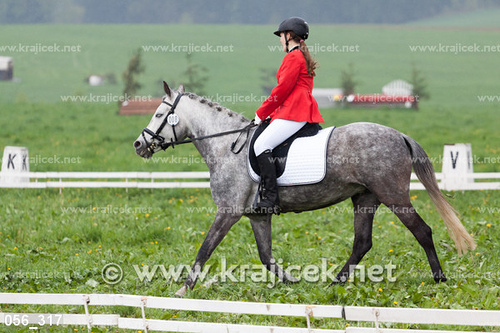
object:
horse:
[133, 79, 479, 283]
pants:
[248, 110, 339, 169]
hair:
[299, 34, 326, 70]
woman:
[247, 16, 328, 213]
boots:
[236, 174, 261, 221]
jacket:
[243, 42, 355, 132]